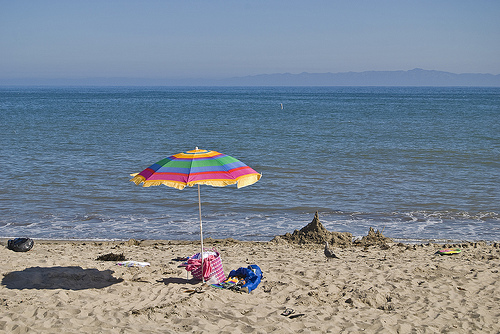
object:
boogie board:
[437, 247, 460, 255]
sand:
[0, 238, 500, 333]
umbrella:
[128, 146, 263, 290]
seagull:
[114, 260, 152, 281]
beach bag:
[185, 250, 232, 285]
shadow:
[2, 266, 125, 292]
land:
[0, 69, 500, 90]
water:
[0, 86, 500, 241]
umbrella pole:
[196, 184, 205, 254]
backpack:
[212, 265, 263, 292]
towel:
[212, 278, 249, 295]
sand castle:
[272, 211, 403, 249]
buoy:
[278, 101, 284, 111]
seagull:
[323, 241, 343, 263]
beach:
[0, 236, 500, 332]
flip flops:
[280, 307, 306, 318]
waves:
[0, 208, 499, 239]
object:
[6, 238, 34, 252]